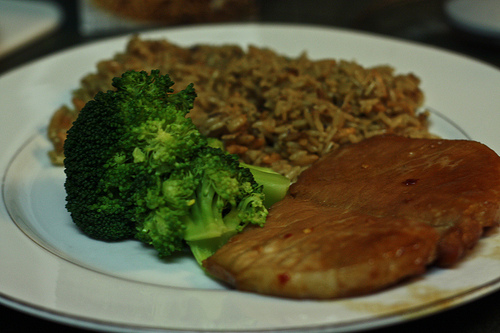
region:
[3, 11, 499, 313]
Cooked food is on a plate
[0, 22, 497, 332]
The plate is white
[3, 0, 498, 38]
Background of the image is blurred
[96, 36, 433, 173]
Cooked rice is on the plate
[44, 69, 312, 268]
Broccoli is on the plate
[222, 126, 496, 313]
Pork chop is on the plate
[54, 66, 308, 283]
Broccoli on the plate is chopped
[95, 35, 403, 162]
Rice is tan colored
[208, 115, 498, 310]
Meat is light brown in color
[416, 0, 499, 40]
A white plate is in the background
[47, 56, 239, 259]
there is brocolli on the plate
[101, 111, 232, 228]
the brocolli is green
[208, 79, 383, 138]
the rice is brown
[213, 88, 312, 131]
the rice is dry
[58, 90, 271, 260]
there are two pieces of brocolli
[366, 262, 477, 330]
there is stain on the plate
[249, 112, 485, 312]
the meat is brown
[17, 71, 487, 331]
the plate is threequater full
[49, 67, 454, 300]
the food looks delicious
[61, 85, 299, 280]
the broccoli is very green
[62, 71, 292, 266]
The pieces of broccoli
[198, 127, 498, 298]
The thin piece of meat on the plate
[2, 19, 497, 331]
The white plate the food is on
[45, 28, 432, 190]
The brown rice on the plate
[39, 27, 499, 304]
The food on the plate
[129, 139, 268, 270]
The smaller of the two pieces of broccoli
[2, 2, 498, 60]
The other plates in the background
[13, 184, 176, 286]
The shadow of the broccoli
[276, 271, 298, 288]
Red mark on the nearest edge of the meat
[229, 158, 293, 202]
The stalk of the larger piece of broccoli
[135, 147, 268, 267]
Piece of green broccoli on a plate.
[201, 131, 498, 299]
Piece of pork on a plate.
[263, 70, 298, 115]
Grains of rice in a pile.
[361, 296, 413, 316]
Grease from the pork on a plate.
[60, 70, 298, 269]
Large chunk of green broccoli on a plate.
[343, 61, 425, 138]
Rice in a pile on a plate.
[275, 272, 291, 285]
Red spice on a piece of pork.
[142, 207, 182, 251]
Piece of broccoli.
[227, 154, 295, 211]
Green broccoli stem.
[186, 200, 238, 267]
Part of a green broccoli stem.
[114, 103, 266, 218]
the broccoli is green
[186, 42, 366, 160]
the rice is cooked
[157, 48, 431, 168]
the rice is brown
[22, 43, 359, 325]
the plate is round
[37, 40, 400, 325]
the plate is white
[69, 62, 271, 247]
the broccoli is steamed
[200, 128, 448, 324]
the meat has sauce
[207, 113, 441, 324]
one meat on the plate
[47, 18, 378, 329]
the food is on the plate